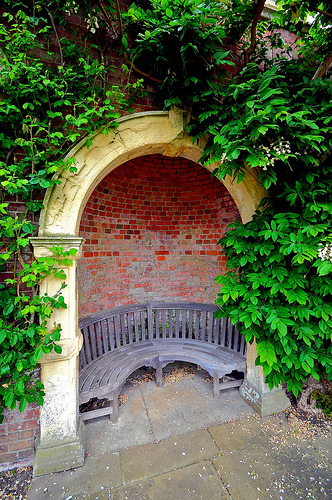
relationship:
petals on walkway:
[2, 422, 324, 472] [3, 386, 331, 496]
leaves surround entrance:
[0, 10, 331, 405] [25, 92, 309, 450]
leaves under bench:
[0, 10, 331, 405] [49, 302, 287, 418]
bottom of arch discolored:
[10, 358, 324, 449] [35, 116, 239, 274]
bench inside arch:
[49, 302, 287, 418] [32, 105, 327, 442]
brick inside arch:
[92, 187, 228, 283] [32, 105, 327, 442]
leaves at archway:
[0, 10, 331, 405] [32, 105, 327, 442]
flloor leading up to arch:
[3, 386, 331, 496] [32, 105, 327, 442]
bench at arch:
[49, 302, 287, 418] [32, 105, 327, 442]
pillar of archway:
[14, 161, 115, 474] [32, 105, 327, 442]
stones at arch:
[35, 92, 312, 476] [32, 105, 327, 442]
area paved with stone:
[3, 386, 331, 496] [169, 437, 248, 498]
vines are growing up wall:
[0, 10, 331, 405] [1, 9, 330, 443]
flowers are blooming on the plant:
[244, 127, 298, 163] [0, 10, 331, 405]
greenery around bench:
[0, 10, 331, 405] [49, 302, 287, 418]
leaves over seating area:
[0, 10, 331, 405] [49, 302, 287, 418]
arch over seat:
[32, 105, 327, 442] [49, 302, 287, 418]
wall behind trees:
[63, 167, 249, 302] [0, 10, 331, 405]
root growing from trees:
[280, 369, 331, 419] [0, 10, 331, 405]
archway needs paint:
[32, 105, 327, 442] [35, 127, 294, 430]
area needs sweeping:
[3, 386, 331, 496] [130, 402, 330, 472]